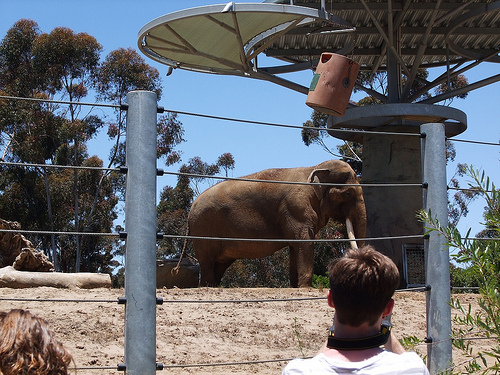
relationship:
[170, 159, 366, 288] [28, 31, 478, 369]
elephant in wild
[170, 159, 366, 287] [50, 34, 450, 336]
elephant in wild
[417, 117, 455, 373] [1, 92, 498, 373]
pole holding wires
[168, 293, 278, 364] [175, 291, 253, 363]
ground made of dirt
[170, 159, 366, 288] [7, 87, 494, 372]
elephant in enclosure